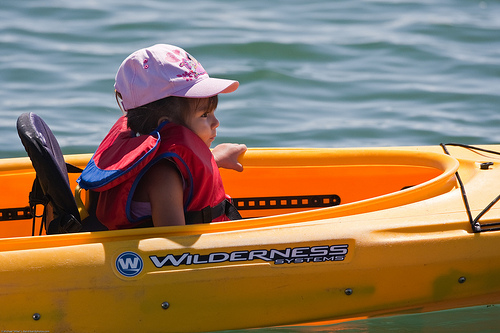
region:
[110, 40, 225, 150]
the head of a child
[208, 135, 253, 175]
the hand of a child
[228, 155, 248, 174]
the thumb of a child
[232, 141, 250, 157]
the finger of a child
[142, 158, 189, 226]
the arm of a child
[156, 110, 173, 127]
the ear of a child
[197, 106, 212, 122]
the eye of a child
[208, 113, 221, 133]
the nose of a child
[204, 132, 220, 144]
the mouth of a child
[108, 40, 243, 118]
a pink baseball cap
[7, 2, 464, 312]
a child sitting in a kayak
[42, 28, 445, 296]
a child sitting in a yellow kayak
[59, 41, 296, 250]
a child wearing a life vest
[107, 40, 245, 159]
a child with a pink cap on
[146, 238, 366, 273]
the Wilderness Systems logo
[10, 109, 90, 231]
the seat on a kayak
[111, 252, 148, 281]
a white W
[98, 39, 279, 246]
A girl in a kayak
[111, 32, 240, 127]
A girl wearing a pink hat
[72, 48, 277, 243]
A girl wearing a life jacket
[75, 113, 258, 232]
A red and blue life jacket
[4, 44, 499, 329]
A yellow kayak on the water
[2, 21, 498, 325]
A little girl in a yellow kayak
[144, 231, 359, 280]
Words on a kayak that say Wilderness Systems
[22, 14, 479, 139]
Water beyond the girl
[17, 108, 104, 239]
a black seat in a kayak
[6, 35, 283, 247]
A girl sitting in a black seat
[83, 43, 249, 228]
a little girl sitting on a kayak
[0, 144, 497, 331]
a yellow kayak on the water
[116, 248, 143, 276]
a white and blue logo on a kayak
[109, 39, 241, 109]
a girl wearing a pink cap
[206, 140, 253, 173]
a girl holding the side of a kayak with her hand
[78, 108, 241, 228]
girl wearing a blue and red life jacket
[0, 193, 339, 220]
black metal on the side of a kayak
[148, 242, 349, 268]
black and white writing on the side of a kayak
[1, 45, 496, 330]
a girl floating on the water in a kayak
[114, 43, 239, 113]
A childs pink hat.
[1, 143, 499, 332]
A plastic yellow boat.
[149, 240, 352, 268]
Black and white lettering.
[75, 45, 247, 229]
A child with a blue and red life vest.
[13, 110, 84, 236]
A black seat back.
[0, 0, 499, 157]
A body of water.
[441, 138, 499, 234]
Stretched black roping.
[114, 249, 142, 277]
Blue and white logo.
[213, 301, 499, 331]
Water under a boat.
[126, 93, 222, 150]
A childs facial profile.